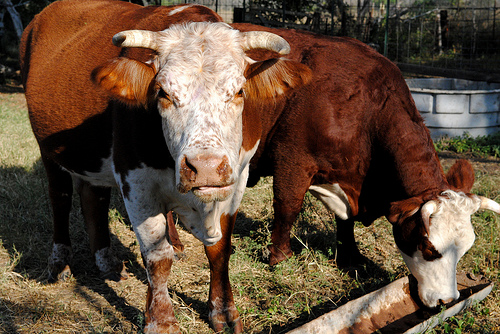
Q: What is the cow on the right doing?
A: Eating.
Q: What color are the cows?
A: Brown.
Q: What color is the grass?
A: Green.